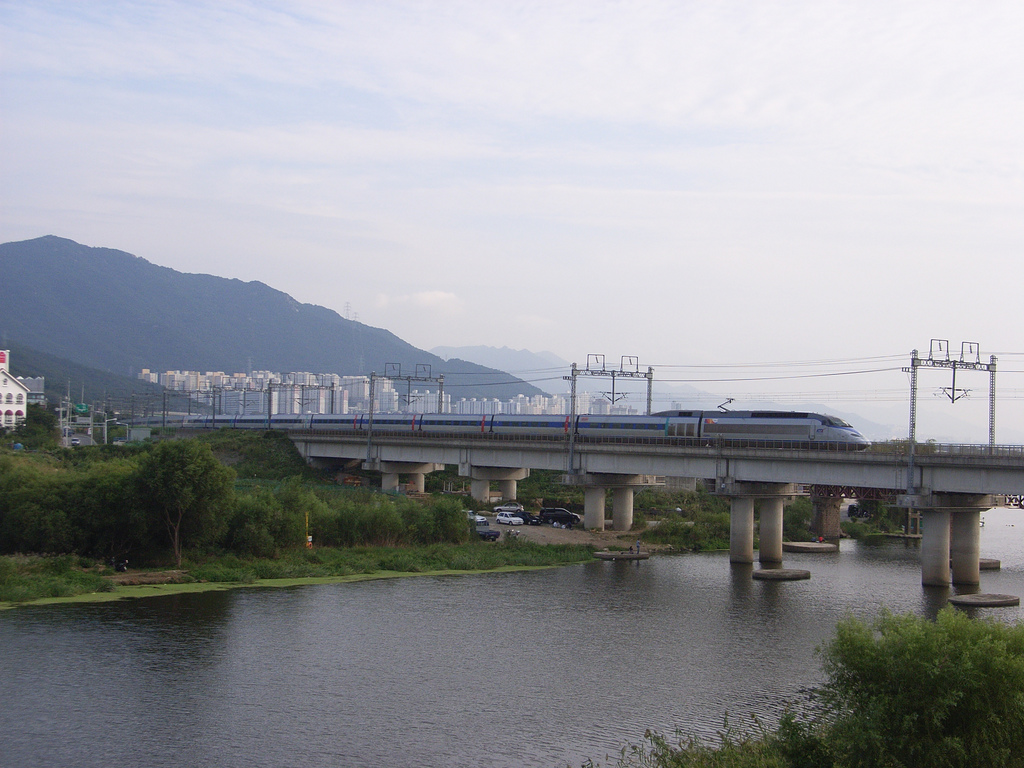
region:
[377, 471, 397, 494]
a solid tan concrete pillar of the bridge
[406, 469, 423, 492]
a solid tan concrete pillar of the bridge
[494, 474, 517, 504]
a solid tan concrete pillar of the bridge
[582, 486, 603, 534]
a solid tan concrete pillar of the bridge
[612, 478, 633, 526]
a solid tan concrete pillar of the bridge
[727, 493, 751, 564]
a solid tan concrete pillar of the bridge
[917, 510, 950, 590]
a solid tan concrete pillar of the bridge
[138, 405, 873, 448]
train travels across bridge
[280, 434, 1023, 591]
bridge underneath train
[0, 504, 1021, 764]
water underneath bridge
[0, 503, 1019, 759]
water underneath train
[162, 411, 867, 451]
train above water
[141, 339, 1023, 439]
power lines behind grey train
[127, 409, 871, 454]
train is grey with blue stripe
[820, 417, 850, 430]
windshield belongs to train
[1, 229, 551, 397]
mountain behind train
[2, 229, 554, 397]
mountain behind concrete bridge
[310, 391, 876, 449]
long silver train over bridge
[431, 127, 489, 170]
white clouds in blue sky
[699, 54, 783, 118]
white clouds in blue sky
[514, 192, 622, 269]
white clouds in blue sky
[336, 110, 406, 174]
white clouds in blue sky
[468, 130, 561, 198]
white clouds in blue sky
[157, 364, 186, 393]
a building in a city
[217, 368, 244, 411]
a building in a city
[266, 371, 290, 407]
a building in a city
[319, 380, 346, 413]
a building in a city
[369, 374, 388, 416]
a building in a city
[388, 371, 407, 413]
a building in a city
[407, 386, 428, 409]
a building in a city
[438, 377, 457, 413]
a building in a city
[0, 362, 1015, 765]
Bridge over a river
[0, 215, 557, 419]
A mountain in the distance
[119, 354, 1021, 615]
Cars under a bridge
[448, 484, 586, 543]
A group of cars